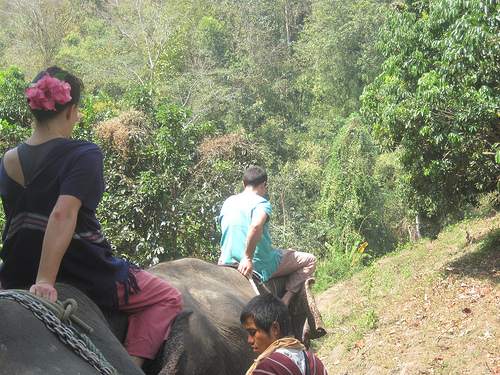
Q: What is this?
A: Elephant.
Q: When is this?
A: Daytime.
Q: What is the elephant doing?
A: Moving.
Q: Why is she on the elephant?
A: Fun.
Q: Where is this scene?
A: On a hill.